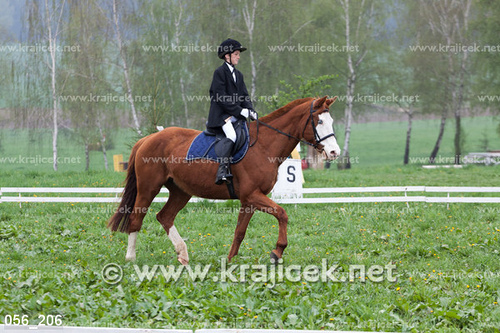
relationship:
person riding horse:
[205, 37, 257, 185] [108, 96, 343, 267]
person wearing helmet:
[205, 37, 257, 185] [216, 36, 246, 60]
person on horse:
[205, 37, 257, 185] [108, 96, 343, 267]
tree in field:
[341, 4, 371, 171] [2, 121, 499, 186]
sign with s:
[277, 157, 305, 200] [286, 164, 297, 184]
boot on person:
[214, 137, 237, 185] [205, 37, 257, 185]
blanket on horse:
[186, 121, 250, 162] [108, 96, 343, 267]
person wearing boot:
[205, 37, 257, 185] [214, 137, 237, 185]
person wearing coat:
[205, 37, 257, 185] [206, 60, 253, 134]